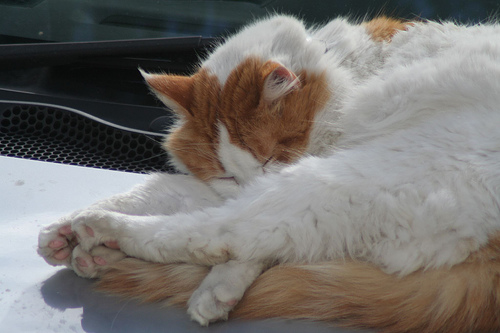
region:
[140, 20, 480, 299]
this is a cat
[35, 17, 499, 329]
the cat is smiling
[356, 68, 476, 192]
the fur is white in color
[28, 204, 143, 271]
these are the legs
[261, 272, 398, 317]
the tail is long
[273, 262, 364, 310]
the tail is brown in color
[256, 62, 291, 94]
this is the ear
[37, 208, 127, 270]
the legs are white in color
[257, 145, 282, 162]
the eye is closed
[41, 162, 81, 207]
this is a table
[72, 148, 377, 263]
the white leg of a cat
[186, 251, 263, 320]
the white leg of a cat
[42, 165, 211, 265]
the white leg of a cat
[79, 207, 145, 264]
the white paw of a cat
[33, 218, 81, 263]
the white paw of a cat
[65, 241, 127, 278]
the white paw of a cat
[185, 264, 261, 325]
the white paw of a cat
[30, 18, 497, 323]
a orange and white long haired cat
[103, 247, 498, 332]
the orange and white tail of a cat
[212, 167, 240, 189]
the closed eye of a cat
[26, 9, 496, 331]
Orange and white cat curled up sleeping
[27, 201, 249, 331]
All four of a cats feet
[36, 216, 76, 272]
Bottom of a cats white paw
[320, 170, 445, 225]
White fur on a cat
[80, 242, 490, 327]
Orange fur on a cats tail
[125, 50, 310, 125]
Orange and white cats ears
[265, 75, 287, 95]
White hair inside a cats ear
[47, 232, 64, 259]
Pink pads on the bottom of a cats feet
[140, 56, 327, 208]
Cat with eyes closed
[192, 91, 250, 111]
Orange fur on a cat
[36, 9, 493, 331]
Cat sound asleep.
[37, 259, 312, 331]
Shadow of the cat on the table.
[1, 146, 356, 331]
Table on which the cat is sleeping.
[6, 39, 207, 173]
Mesh table behind the cat.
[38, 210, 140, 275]
Three of cat's paws together.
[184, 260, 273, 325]
One paw separate from others.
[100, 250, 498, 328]
Cat's tail along the body.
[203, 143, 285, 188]
Cat's eyes closed.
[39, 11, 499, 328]
Majority of cat is white.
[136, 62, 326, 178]
Ears and part of face are brown.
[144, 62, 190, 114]
Cat has tan ear.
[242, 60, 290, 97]
Cat has tan ear.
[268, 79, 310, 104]
White hair on inside of ear.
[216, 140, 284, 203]
Cat has eyes closed.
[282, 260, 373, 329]
Cat has white and tan tail.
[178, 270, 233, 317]
Cat has white paw.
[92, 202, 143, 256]
Cat has white paw.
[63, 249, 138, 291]
Cat has white paw.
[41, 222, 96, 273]
Pink pads on paw.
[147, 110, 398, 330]
Cat is sleeping.